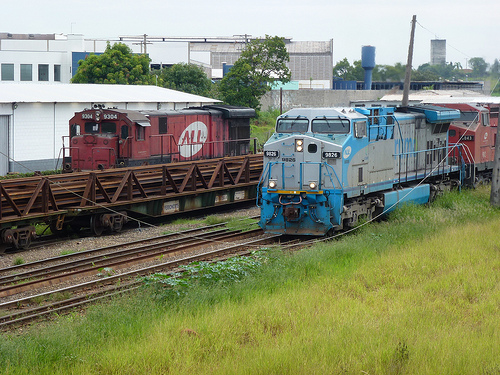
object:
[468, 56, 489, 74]
tree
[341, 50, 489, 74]
horizon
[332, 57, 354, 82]
tree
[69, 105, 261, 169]
engine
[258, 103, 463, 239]
engine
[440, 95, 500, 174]
red engine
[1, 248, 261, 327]
tracks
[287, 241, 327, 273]
grass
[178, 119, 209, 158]
logo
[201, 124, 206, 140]
white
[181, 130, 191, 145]
red letters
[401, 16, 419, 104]
pole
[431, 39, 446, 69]
silo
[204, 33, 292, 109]
trees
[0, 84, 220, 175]
building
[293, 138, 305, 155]
headlights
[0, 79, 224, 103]
roof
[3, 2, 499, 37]
sky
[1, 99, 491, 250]
wire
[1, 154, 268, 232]
platform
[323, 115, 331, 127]
wipers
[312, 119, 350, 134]
windshield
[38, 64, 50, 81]
windows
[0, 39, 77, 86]
building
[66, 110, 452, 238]
two trains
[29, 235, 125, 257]
gravel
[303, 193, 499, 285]
slope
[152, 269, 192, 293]
bush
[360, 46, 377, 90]
water tower